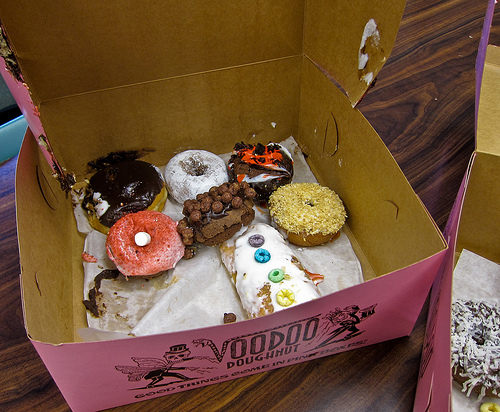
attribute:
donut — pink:
[106, 212, 181, 276]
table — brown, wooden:
[2, 0, 499, 409]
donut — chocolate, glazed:
[79, 155, 175, 238]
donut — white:
[63, 99, 343, 346]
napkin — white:
[153, 283, 215, 325]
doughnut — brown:
[78, 162, 173, 234]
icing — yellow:
[271, 182, 348, 234]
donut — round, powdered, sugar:
[162, 137, 232, 212]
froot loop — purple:
[250, 231, 265, 247]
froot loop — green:
[265, 266, 285, 282]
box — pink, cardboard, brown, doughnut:
[3, 10, 453, 407]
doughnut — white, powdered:
[162, 146, 227, 203]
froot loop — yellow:
[273, 285, 297, 307]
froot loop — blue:
[252, 246, 271, 263]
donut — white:
[218, 219, 324, 319]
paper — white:
[70, 133, 366, 349]